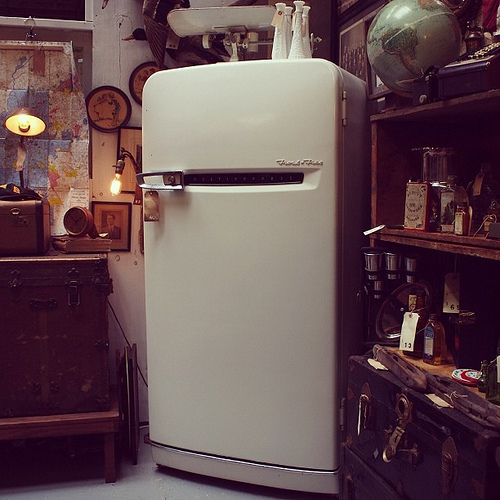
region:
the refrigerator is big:
[100, 38, 353, 490]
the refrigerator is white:
[107, 44, 354, 481]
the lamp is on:
[2, 85, 84, 287]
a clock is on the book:
[21, 184, 115, 256]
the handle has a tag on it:
[122, 147, 192, 240]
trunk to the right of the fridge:
[317, 341, 482, 489]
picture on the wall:
[64, 182, 138, 265]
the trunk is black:
[316, 345, 493, 496]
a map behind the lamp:
[1, 41, 99, 219]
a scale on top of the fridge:
[168, 0, 282, 55]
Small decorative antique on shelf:
[389, 172, 432, 237]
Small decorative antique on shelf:
[414, 309, 451, 370]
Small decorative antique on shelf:
[389, 281, 428, 379]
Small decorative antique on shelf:
[350, 19, 477, 93]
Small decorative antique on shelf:
[61, 199, 99, 237]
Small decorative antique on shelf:
[50, 224, 118, 256]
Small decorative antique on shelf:
[0, 180, 60, 261]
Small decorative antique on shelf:
[435, 51, 495, 112]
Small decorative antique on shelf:
[445, 306, 480, 390]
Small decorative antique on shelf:
[362, 327, 429, 398]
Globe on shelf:
[367, 1, 469, 108]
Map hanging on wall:
[2, 41, 73, 190]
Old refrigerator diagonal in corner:
[132, 58, 364, 484]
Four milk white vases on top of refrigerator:
[265, 3, 318, 60]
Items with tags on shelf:
[358, 220, 466, 417]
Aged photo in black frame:
[92, 199, 131, 246]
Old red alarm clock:
[61, 204, 93, 236]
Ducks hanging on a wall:
[118, 0, 177, 60]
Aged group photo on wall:
[337, 20, 369, 83]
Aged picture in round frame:
[83, 84, 131, 134]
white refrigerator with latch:
[128, 77, 363, 497]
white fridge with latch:
[130, 159, 200, 227]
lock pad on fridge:
[123, 155, 193, 225]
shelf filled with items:
[357, 78, 498, 382]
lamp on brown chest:
[4, 80, 59, 265]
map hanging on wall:
[0, 74, 105, 229]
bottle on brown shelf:
[397, 289, 439, 359]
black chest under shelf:
[335, 340, 492, 496]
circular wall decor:
[80, 80, 136, 137]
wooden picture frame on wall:
[94, 191, 134, 259]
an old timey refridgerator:
[112, 59, 372, 476]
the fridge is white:
[163, 55, 353, 494]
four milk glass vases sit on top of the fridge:
[264, 3, 310, 58]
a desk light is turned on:
[2, 87, 49, 206]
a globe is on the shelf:
[370, 0, 471, 100]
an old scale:
[165, 0, 275, 72]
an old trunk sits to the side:
[1, 249, 126, 427]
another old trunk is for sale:
[348, 351, 499, 488]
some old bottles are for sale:
[406, 178, 477, 238]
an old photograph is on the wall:
[332, 23, 375, 79]